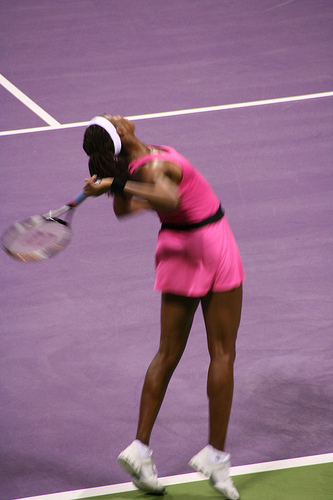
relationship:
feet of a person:
[114, 435, 260, 498] [83, 95, 265, 499]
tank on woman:
[126, 142, 216, 226] [41, 102, 256, 492]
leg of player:
[189, 277, 249, 498] [79, 116, 244, 500]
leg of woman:
[139, 280, 197, 446] [74, 74, 274, 498]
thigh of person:
[196, 281, 249, 357] [47, 101, 249, 478]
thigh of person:
[199, 281, 244, 339] [39, 88, 293, 378]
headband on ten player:
[95, 161, 116, 219] [138, 303, 236, 438]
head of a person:
[82, 111, 133, 158] [80, 110, 238, 498]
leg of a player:
[202, 281, 243, 446] [79, 116, 244, 500]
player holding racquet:
[79, 116, 244, 500] [2, 176, 100, 264]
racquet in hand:
[2, 176, 100, 264] [83, 172, 111, 197]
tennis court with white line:
[0, 0, 333, 499] [139, 89, 333, 123]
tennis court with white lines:
[119, 15, 213, 75] [7, 59, 328, 146]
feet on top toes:
[192, 444, 238, 498] [148, 476, 172, 498]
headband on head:
[85, 115, 122, 159] [69, 92, 142, 165]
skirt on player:
[149, 220, 252, 300] [85, 97, 257, 292]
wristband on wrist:
[108, 174, 129, 194] [109, 177, 129, 192]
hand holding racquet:
[94, 165, 201, 237] [2, 176, 100, 264]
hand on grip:
[83, 172, 111, 197] [67, 180, 102, 204]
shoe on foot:
[187, 443, 240, 499] [122, 443, 164, 491]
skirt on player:
[149, 220, 252, 300] [79, 116, 244, 500]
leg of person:
[136, 294, 197, 442] [22, 89, 270, 467]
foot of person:
[115, 440, 167, 494] [66, 106, 274, 492]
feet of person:
[192, 444, 238, 498] [66, 106, 274, 492]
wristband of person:
[108, 174, 129, 194] [80, 110, 238, 498]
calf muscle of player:
[142, 358, 167, 398] [79, 116, 244, 500]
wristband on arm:
[108, 174, 129, 194] [78, 174, 199, 216]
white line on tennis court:
[139, 89, 333, 123] [0, 0, 333, 499]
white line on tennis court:
[143, 88, 325, 130] [0, 0, 333, 499]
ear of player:
[115, 125, 126, 136] [79, 116, 244, 500]